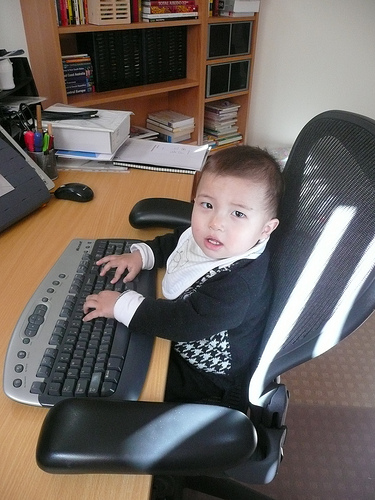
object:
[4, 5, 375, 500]
photo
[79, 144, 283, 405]
boy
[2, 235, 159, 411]
keyboard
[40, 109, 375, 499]
chair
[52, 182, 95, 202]
mouse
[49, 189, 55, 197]
cord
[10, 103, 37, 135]
scissors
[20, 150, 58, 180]
holder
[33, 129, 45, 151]
markers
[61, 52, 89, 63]
books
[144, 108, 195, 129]
books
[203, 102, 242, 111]
books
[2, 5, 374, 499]
home office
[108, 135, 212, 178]
folder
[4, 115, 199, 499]
desk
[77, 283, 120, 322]
hands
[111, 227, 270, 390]
shirt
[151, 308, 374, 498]
floor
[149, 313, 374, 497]
carpet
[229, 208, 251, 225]
eyes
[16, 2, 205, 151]
bookshelf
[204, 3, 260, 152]
bookshelf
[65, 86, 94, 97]
books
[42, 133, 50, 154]
office supplies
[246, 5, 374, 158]
wall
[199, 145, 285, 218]
brown hair